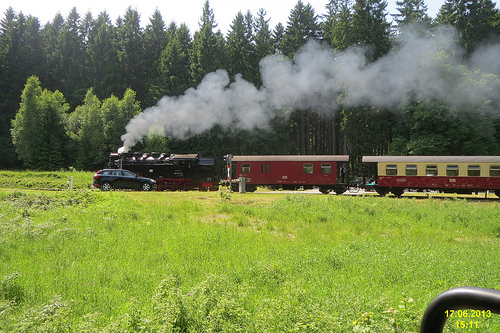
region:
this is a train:
[162, 154, 217, 187]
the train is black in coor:
[161, 161, 210, 186]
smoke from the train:
[136, 75, 239, 141]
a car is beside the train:
[91, 168, 155, 188]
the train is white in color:
[162, 86, 229, 129]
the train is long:
[243, 158, 495, 189]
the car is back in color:
[90, 171, 155, 191]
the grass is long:
[3, 224, 410, 331]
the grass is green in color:
[8, 215, 403, 328]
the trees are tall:
[0, 22, 174, 92]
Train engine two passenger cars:
[109, 136, 484, 191]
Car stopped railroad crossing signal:
[88, 158, 254, 198]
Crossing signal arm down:
[212, 149, 251, 198]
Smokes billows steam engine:
[105, 109, 225, 166]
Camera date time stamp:
[422, 297, 499, 331]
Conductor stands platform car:
[333, 157, 355, 189]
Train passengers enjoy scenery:
[364, 152, 499, 194]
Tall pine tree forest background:
[8, 4, 103, 168]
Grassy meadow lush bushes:
[31, 244, 411, 327]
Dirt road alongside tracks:
[2, 177, 134, 194]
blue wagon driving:
[95, 154, 157, 196]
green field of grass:
[126, 232, 315, 327]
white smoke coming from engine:
[109, 86, 445, 131]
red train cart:
[219, 140, 366, 211]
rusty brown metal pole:
[412, 272, 468, 328]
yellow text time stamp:
[439, 303, 478, 327]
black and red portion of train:
[102, 139, 223, 198]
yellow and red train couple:
[355, 141, 489, 217]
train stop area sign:
[222, 168, 247, 190]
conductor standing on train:
[333, 157, 364, 200]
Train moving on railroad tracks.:
[109, 150, 499, 196]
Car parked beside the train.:
[90, 166, 156, 193]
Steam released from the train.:
[120, 25, 495, 150]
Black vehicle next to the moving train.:
[93, 167, 155, 194]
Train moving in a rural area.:
[105, 0, 499, 275]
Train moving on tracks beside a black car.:
[0, 148, 498, 200]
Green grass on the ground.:
[25, 205, 407, 307]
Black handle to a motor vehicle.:
[420, 287, 498, 332]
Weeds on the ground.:
[127, 278, 267, 331]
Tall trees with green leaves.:
[2, 5, 497, 166]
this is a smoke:
[213, 70, 409, 122]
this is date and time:
[438, 306, 493, 331]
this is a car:
[88, 166, 170, 190]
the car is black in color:
[90, 168, 160, 191]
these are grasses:
[125, 222, 341, 296]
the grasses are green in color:
[103, 224, 329, 296]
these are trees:
[0, 12, 263, 154]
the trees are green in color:
[8, 12, 121, 135]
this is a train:
[107, 146, 489, 192]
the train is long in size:
[102, 147, 494, 189]